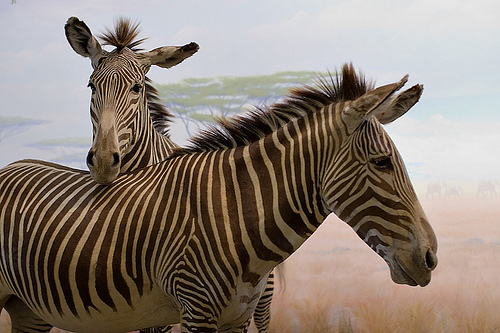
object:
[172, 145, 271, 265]
stripes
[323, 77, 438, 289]
face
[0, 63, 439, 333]
zebras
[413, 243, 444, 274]
nose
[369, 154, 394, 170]
eye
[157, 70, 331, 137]
tree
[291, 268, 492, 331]
grass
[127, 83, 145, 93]
eyes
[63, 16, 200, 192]
zebra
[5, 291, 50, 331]
leg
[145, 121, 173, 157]
stripes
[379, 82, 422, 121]
ears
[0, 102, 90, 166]
trees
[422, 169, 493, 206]
animals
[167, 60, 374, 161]
hair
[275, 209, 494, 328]
field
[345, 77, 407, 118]
ear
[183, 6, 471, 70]
sky